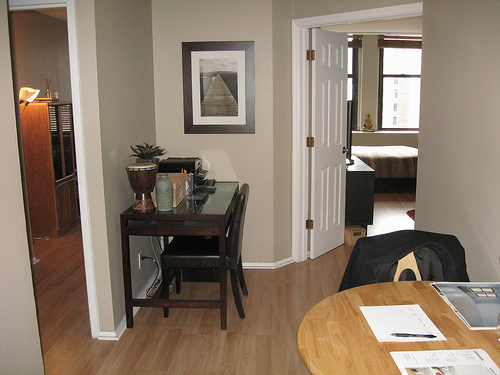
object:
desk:
[119, 181, 241, 333]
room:
[92, 0, 500, 374]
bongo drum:
[123, 161, 159, 215]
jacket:
[336, 229, 471, 292]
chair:
[337, 229, 471, 292]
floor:
[119, 262, 338, 373]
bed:
[350, 145, 419, 189]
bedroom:
[307, 16, 428, 255]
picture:
[181, 41, 254, 135]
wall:
[149, 1, 273, 270]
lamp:
[13, 85, 39, 114]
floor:
[30, 218, 90, 323]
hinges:
[305, 49, 313, 62]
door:
[305, 26, 348, 260]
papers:
[428, 281, 500, 331]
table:
[294, 281, 499, 373]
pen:
[389, 332, 436, 338]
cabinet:
[18, 97, 82, 238]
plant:
[128, 142, 169, 174]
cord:
[141, 252, 175, 299]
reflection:
[50, 103, 76, 182]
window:
[48, 104, 74, 133]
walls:
[0, 1, 499, 284]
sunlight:
[381, 45, 421, 129]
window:
[345, 33, 428, 131]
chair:
[159, 183, 248, 317]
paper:
[357, 303, 447, 343]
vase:
[155, 169, 173, 212]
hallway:
[0, 0, 91, 375]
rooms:
[6, 0, 498, 374]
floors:
[32, 164, 499, 373]